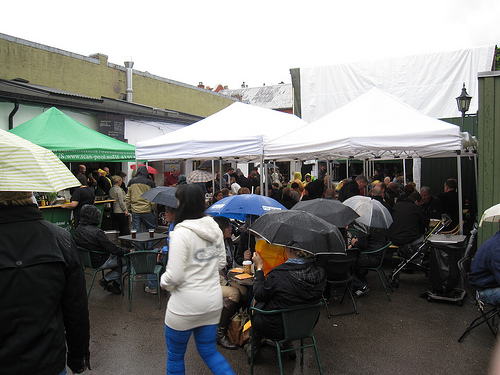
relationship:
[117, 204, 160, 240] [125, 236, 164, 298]
drink on table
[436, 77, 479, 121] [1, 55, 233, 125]
light on building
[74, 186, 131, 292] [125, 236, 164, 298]
man in front of table